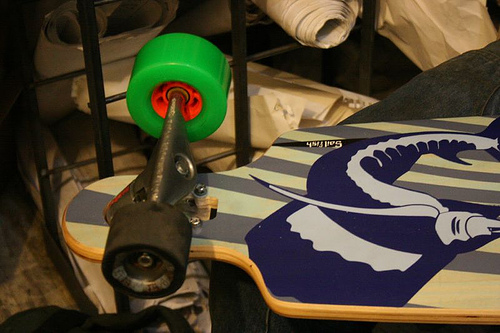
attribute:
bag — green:
[0, 305, 193, 331]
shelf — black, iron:
[12, 0, 379, 331]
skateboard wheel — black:
[84, 173, 206, 331]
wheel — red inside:
[123, 31, 228, 141]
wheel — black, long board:
[97, 205, 197, 311]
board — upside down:
[52, 23, 496, 320]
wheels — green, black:
[84, 31, 222, 300]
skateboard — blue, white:
[98, 137, 485, 285]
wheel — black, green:
[120, 28, 235, 151]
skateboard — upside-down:
[53, 29, 498, 327]